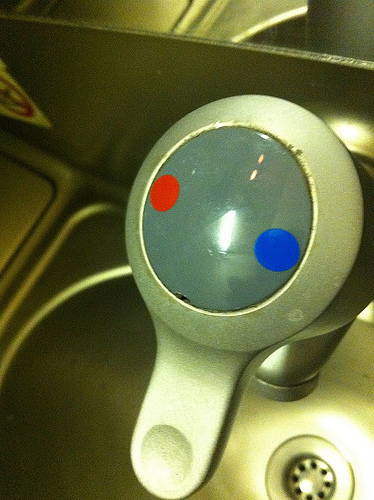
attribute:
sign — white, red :
[5, 57, 52, 133]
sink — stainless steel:
[2, 195, 371, 499]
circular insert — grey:
[140, 126, 312, 313]